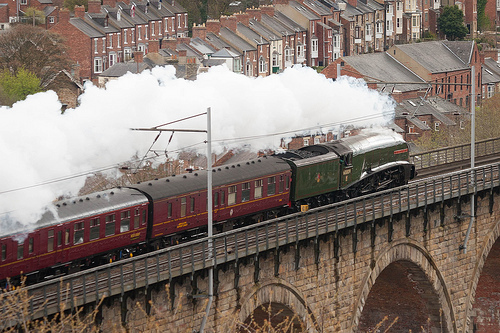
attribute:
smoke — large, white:
[1, 71, 392, 175]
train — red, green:
[1, 130, 410, 257]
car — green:
[286, 131, 344, 217]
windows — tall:
[74, 219, 106, 247]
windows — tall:
[113, 207, 141, 233]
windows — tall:
[176, 197, 200, 222]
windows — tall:
[227, 179, 289, 202]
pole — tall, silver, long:
[205, 105, 215, 277]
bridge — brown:
[7, 190, 499, 332]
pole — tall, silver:
[467, 65, 484, 233]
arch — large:
[347, 235, 452, 329]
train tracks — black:
[172, 216, 321, 264]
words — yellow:
[174, 219, 195, 232]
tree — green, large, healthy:
[436, 5, 472, 46]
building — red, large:
[51, 11, 113, 80]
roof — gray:
[73, 15, 103, 41]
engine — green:
[337, 138, 414, 203]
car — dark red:
[150, 156, 289, 239]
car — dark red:
[5, 192, 149, 286]